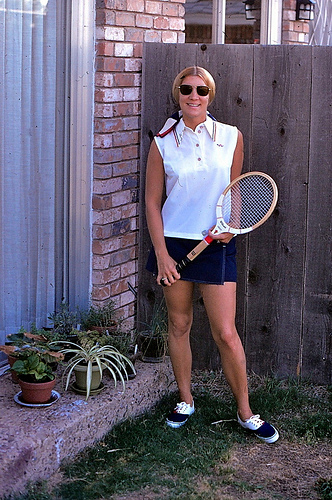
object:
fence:
[142, 45, 332, 381]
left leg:
[201, 281, 252, 420]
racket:
[159, 170, 281, 287]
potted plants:
[136, 296, 169, 358]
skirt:
[144, 237, 237, 289]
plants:
[48, 340, 137, 401]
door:
[0, 0, 92, 356]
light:
[293, 0, 315, 23]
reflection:
[242, 0, 260, 19]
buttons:
[197, 129, 201, 134]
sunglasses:
[177, 84, 211, 96]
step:
[1, 339, 182, 499]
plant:
[14, 352, 64, 379]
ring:
[216, 240, 220, 244]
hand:
[208, 221, 234, 244]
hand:
[157, 253, 181, 288]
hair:
[172, 66, 216, 106]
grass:
[0, 378, 331, 499]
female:
[147, 65, 283, 447]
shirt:
[153, 116, 238, 242]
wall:
[90, 17, 143, 328]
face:
[177, 74, 209, 118]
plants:
[4, 332, 30, 344]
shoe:
[236, 409, 279, 443]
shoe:
[167, 399, 195, 430]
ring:
[162, 277, 167, 280]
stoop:
[0, 346, 178, 498]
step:
[0, 354, 178, 497]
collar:
[172, 115, 216, 149]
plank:
[136, 40, 197, 358]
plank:
[195, 41, 252, 370]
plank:
[244, 40, 312, 393]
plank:
[299, 48, 332, 384]